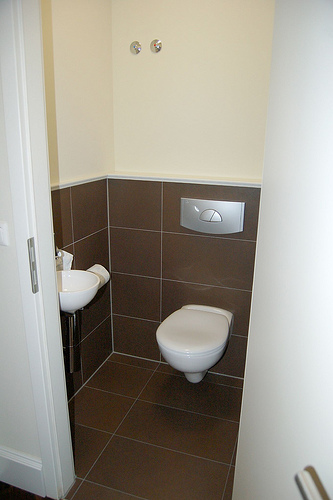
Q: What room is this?
A: The bathroom.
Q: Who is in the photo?
A: Nobody.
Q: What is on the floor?
A: Tile.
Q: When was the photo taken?
A: Daytime.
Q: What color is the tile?
A: Brown.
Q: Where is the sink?
A: On the wall.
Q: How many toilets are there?
A: One.